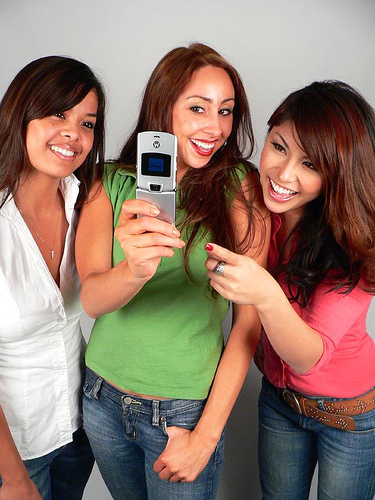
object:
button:
[152, 141, 160, 149]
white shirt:
[0, 169, 88, 465]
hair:
[113, 43, 270, 294]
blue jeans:
[20, 427, 97, 499]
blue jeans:
[82, 367, 225, 499]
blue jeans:
[256, 375, 375, 499]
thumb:
[166, 425, 181, 439]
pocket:
[156, 419, 199, 459]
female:
[203, 80, 375, 500]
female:
[74, 42, 271, 500]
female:
[0, 55, 106, 500]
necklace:
[14, 199, 62, 260]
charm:
[50, 249, 55, 260]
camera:
[135, 131, 178, 227]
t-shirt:
[78, 152, 258, 403]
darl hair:
[266, 78, 375, 310]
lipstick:
[188, 137, 219, 157]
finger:
[203, 242, 241, 264]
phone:
[136, 131, 178, 228]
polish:
[204, 244, 213, 252]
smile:
[188, 137, 220, 157]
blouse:
[0, 175, 85, 460]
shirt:
[252, 204, 375, 399]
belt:
[274, 385, 374, 432]